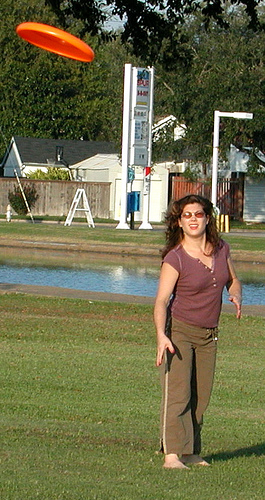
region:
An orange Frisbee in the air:
[10, 10, 91, 75]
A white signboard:
[51, 182, 105, 238]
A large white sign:
[108, 56, 157, 236]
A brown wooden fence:
[0, 164, 164, 221]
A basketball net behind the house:
[39, 139, 81, 181]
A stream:
[5, 254, 159, 296]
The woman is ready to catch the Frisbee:
[139, 183, 251, 492]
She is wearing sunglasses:
[142, 187, 238, 251]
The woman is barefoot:
[147, 436, 226, 483]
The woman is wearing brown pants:
[140, 178, 251, 492]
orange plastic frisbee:
[10, 19, 101, 65]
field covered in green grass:
[26, 356, 137, 420]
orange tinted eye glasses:
[178, 210, 207, 219]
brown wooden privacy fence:
[41, 181, 64, 217]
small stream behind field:
[56, 250, 130, 289]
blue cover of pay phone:
[126, 189, 139, 209]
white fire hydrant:
[2, 203, 13, 220]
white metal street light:
[205, 106, 252, 199]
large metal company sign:
[119, 56, 152, 167]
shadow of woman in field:
[204, 427, 263, 471]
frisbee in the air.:
[13, 14, 103, 73]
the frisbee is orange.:
[12, 14, 102, 66]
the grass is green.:
[1, 279, 259, 498]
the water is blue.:
[0, 254, 264, 309]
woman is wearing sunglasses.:
[178, 209, 206, 217]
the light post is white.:
[202, 104, 253, 215]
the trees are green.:
[2, 1, 263, 175]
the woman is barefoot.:
[160, 444, 211, 473]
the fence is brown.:
[0, 169, 115, 225]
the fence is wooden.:
[0, 173, 116, 223]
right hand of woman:
[151, 339, 182, 382]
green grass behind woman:
[65, 374, 138, 436]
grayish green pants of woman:
[159, 350, 220, 420]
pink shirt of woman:
[182, 282, 228, 310]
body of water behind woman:
[40, 251, 147, 310]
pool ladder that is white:
[60, 178, 98, 235]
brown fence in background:
[27, 180, 83, 211]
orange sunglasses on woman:
[171, 204, 209, 233]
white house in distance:
[5, 150, 38, 183]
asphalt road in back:
[229, 220, 254, 243]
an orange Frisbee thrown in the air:
[15, 21, 94, 63]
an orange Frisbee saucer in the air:
[16, 20, 94, 62]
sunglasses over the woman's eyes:
[178, 209, 206, 218]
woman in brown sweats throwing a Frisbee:
[152, 194, 241, 469]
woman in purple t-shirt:
[154, 193, 241, 468]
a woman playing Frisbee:
[154, 193, 241, 468]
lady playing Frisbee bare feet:
[152, 193, 242, 468]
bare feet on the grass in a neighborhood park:
[159, 454, 210, 469]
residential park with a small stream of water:
[0, 243, 263, 498]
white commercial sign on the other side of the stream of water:
[115, 62, 153, 228]